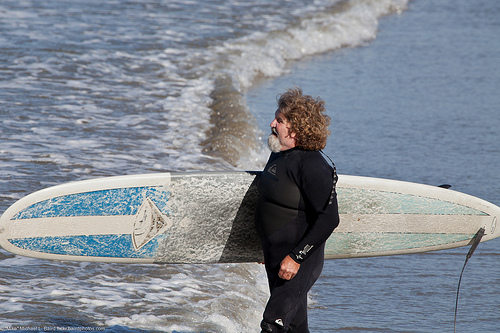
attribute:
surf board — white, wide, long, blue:
[4, 164, 498, 271]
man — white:
[243, 77, 345, 333]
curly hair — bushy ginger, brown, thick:
[275, 80, 338, 154]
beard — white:
[263, 133, 285, 157]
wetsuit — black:
[244, 145, 349, 333]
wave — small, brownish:
[152, 1, 272, 170]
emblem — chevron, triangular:
[126, 193, 176, 254]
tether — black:
[444, 216, 495, 329]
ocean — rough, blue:
[3, 1, 247, 326]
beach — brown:
[320, 6, 500, 331]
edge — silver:
[163, 163, 260, 182]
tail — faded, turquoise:
[343, 183, 487, 255]